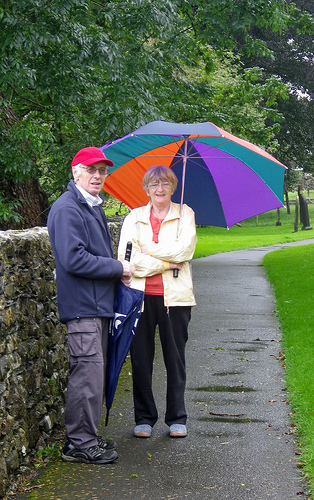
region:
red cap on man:
[69, 143, 103, 169]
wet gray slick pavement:
[223, 304, 245, 321]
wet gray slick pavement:
[171, 479, 190, 498]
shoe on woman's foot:
[136, 423, 149, 439]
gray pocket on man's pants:
[64, 324, 98, 357]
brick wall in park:
[0, 238, 55, 469]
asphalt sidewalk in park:
[209, 259, 275, 493]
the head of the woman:
[143, 169, 174, 203]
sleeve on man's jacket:
[73, 253, 116, 272]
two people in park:
[45, 113, 293, 464]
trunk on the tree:
[3, 183, 44, 225]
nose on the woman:
[158, 188, 164, 192]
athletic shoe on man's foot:
[61, 442, 118, 462]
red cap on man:
[76, 147, 106, 161]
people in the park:
[46, 115, 290, 464]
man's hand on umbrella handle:
[121, 238, 134, 277]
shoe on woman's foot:
[169, 423, 189, 435]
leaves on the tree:
[5, 4, 308, 120]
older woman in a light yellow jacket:
[116, 165, 197, 436]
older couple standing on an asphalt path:
[45, 146, 196, 465]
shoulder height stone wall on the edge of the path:
[0, 215, 123, 498]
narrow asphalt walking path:
[22, 235, 312, 498]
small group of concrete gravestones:
[291, 191, 310, 230]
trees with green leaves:
[0, 110, 312, 229]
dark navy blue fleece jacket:
[47, 179, 121, 318]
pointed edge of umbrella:
[101, 404, 112, 425]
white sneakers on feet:
[120, 418, 187, 438]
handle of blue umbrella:
[118, 237, 135, 270]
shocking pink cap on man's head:
[63, 144, 117, 167]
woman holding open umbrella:
[102, 103, 294, 207]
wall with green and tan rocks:
[14, 246, 54, 426]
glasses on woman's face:
[138, 180, 190, 193]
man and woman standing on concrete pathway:
[45, 114, 288, 463]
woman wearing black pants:
[124, 295, 188, 425]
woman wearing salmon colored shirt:
[147, 212, 172, 298]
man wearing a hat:
[52, 147, 138, 461]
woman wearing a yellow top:
[121, 164, 208, 435]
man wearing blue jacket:
[47, 141, 111, 421]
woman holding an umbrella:
[138, 160, 188, 450]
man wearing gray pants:
[43, 147, 129, 471]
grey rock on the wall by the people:
[34, 298, 41, 315]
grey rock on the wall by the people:
[34, 408, 58, 431]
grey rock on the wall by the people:
[33, 397, 46, 417]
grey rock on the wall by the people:
[31, 368, 44, 386]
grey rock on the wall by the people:
[3, 349, 22, 369]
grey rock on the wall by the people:
[8, 371, 24, 389]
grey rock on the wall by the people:
[11, 425, 31, 452]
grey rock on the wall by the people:
[18, 292, 34, 321]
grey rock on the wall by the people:
[16, 264, 32, 286]